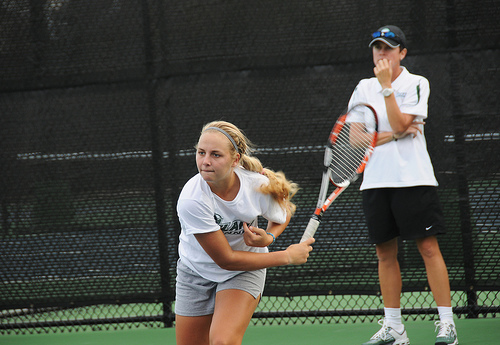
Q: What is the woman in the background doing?
A: Watching the other woman.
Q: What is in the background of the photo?
A: A fence.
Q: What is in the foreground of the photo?
A: A woman playing tennis.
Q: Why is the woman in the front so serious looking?
A: She is trying to play tennis well.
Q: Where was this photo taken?
A: At a tennis court.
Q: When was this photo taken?
A: Daytime.